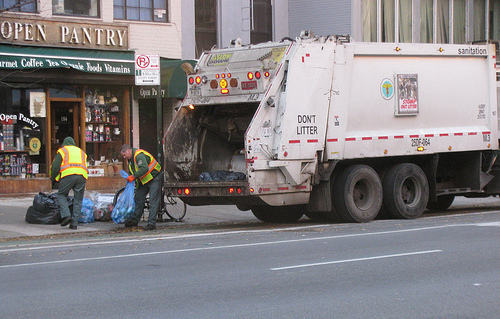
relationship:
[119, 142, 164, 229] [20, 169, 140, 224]
man collecting garbage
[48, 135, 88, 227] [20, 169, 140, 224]
man collecting garbage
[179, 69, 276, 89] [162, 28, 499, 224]
lights on back of whiite truck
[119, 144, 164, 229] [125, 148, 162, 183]
man wears vest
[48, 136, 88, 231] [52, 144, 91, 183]
man wears vest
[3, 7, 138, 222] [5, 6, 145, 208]
coffee shop in building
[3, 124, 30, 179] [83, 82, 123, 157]
sale items on store window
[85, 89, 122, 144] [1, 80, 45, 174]
sale items on store window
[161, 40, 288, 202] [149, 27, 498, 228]
garbage compactor on back of truck